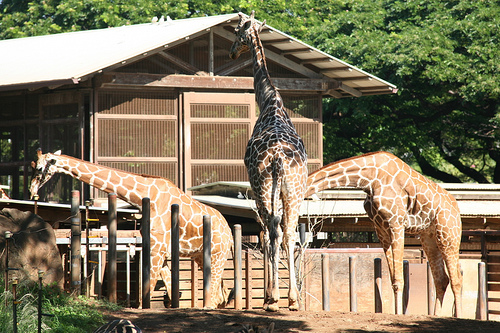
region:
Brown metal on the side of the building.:
[95, 85, 324, 194]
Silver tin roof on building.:
[0, 12, 254, 84]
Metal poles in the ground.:
[66, 186, 243, 313]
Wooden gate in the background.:
[155, 245, 299, 310]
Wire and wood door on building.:
[182, 89, 254, 190]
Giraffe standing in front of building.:
[230, 10, 312, 312]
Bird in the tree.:
[467, 158, 480, 171]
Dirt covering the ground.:
[111, 301, 496, 331]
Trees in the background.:
[320, 0, 496, 185]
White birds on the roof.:
[146, 13, 175, 26]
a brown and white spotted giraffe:
[24, 148, 231, 302]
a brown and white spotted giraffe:
[306, 152, 466, 318]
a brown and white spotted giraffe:
[219, 7, 310, 311]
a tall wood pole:
[67, 187, 81, 297]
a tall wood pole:
[104, 190, 115, 301]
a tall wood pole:
[136, 195, 149, 306]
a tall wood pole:
[201, 212, 211, 304]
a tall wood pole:
[170, 200, 180, 306]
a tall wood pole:
[229, 223, 243, 308]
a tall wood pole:
[318, 250, 330, 308]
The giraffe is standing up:
[23, 149, 240, 315]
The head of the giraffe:
[21, 145, 66, 200]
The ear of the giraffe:
[43, 150, 60, 174]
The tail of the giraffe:
[263, 152, 290, 269]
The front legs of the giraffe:
[375, 231, 408, 315]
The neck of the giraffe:
[246, 44, 286, 106]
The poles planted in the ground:
[61, 190, 253, 315]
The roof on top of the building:
[3, 8, 403, 107]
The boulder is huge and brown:
[3, 202, 70, 300]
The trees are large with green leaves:
[279, 3, 497, 168]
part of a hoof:
[278, 288, 303, 318]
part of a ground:
[343, 312, 365, 327]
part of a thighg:
[215, 240, 233, 266]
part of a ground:
[351, 306, 363, 318]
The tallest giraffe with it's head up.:
[231, 9, 308, 310]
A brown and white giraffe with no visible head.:
[305, 150, 463, 317]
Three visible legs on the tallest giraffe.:
[252, 193, 302, 311]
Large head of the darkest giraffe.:
[227, 8, 267, 60]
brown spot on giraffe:
[77, 165, 89, 172]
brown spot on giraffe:
[95, 168, 110, 181]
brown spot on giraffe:
[91, 177, 103, 189]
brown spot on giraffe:
[104, 182, 116, 194]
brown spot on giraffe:
[371, 180, 382, 195]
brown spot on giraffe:
[377, 167, 392, 183]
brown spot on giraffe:
[408, 176, 426, 191]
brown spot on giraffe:
[378, 207, 391, 224]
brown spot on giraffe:
[256, 150, 263, 160]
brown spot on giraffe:
[296, 190, 301, 196]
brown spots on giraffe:
[44, 144, 164, 215]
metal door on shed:
[102, 98, 181, 196]